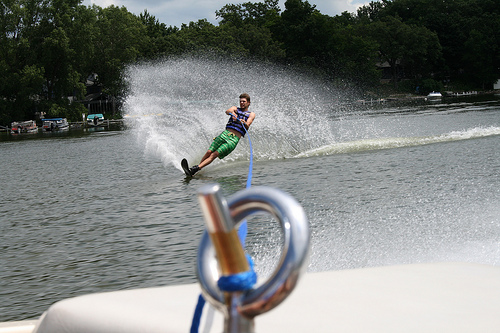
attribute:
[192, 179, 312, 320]
ring — steel, silver, circular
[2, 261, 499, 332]
boat — white, here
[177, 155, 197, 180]
water skiis — black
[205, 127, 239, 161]
swim trunks — green, striped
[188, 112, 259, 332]
rope — blue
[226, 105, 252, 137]
vest — blue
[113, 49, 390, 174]
splash — high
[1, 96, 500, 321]
water — brown, gray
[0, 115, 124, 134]
dock — are moored, dark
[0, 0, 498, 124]
trees — tall, green